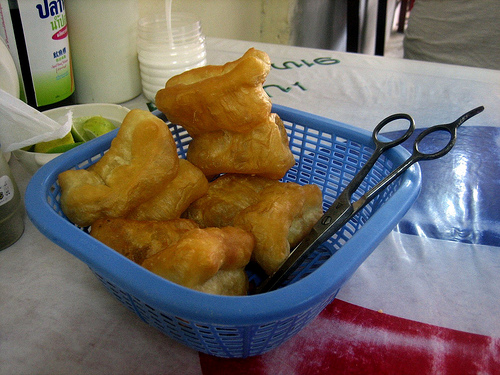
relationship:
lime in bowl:
[40, 120, 125, 156] [20, 94, 135, 170]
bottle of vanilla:
[1, 0, 78, 110] [2, 1, 74, 111]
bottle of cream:
[136, 14, 208, 104] [135, 11, 205, 104]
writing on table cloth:
[268, 32, 345, 108] [2, 35, 496, 373]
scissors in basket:
[267, 102, 482, 292] [16, 83, 428, 363]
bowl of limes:
[17, 102, 140, 178] [23, 117, 112, 152]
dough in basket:
[70, 48, 324, 311] [16, 83, 428, 363]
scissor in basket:
[255, 100, 484, 290] [16, 83, 428, 363]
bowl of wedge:
[17, 102, 140, 178] [74, 117, 119, 146]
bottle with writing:
[1, 0, 78, 110] [34, 0, 71, 31]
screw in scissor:
[322, 214, 335, 226] [255, 100, 484, 290]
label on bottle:
[17, 0, 77, 108] [1, 0, 83, 110]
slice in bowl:
[68, 115, 119, 145] [17, 102, 140, 178]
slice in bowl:
[25, 128, 73, 150] [17, 102, 140, 178]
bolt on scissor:
[317, 213, 335, 226] [255, 100, 484, 290]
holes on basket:
[306, 135, 317, 141] [16, 83, 428, 363]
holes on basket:
[342, 172, 352, 180] [16, 83, 428, 363]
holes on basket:
[292, 125, 303, 130] [16, 83, 428, 363]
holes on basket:
[322, 186, 335, 197] [16, 83, 428, 363]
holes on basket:
[286, 174, 295, 179] [16, 83, 428, 363]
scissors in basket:
[281, 89, 490, 277] [16, 83, 428, 363]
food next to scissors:
[112, 103, 269, 341] [287, 111, 481, 223]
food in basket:
[59, 47, 317, 309] [16, 83, 428, 363]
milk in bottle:
[139, 39, 205, 104] [136, 12, 208, 104]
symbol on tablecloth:
[196, 124, 498, 373] [0, 35, 500, 373]